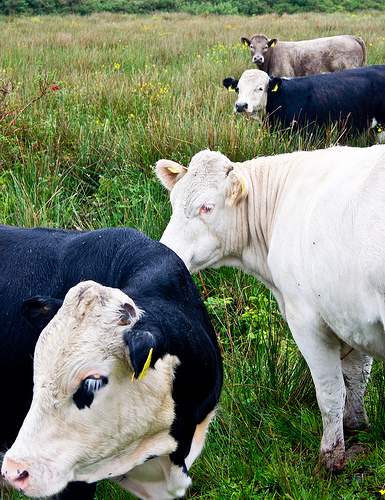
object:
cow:
[240, 34, 366, 79]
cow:
[155, 144, 385, 477]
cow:
[222, 65, 385, 141]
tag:
[130, 347, 154, 383]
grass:
[0, 10, 385, 500]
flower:
[0, 9, 385, 345]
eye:
[250, 44, 268, 53]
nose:
[254, 55, 264, 62]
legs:
[287, 319, 372, 454]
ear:
[240, 36, 276, 47]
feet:
[317, 425, 369, 472]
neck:
[231, 152, 283, 287]